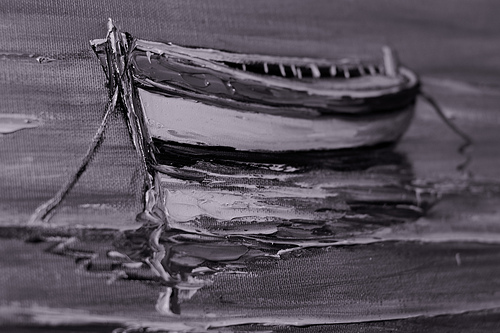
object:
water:
[46, 158, 497, 319]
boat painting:
[1, 0, 500, 333]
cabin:
[218, 60, 382, 80]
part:
[87, 17, 160, 174]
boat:
[87, 15, 422, 154]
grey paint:
[6, 44, 99, 120]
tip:
[105, 16, 119, 34]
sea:
[2, 1, 497, 333]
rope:
[28, 84, 123, 226]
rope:
[417, 84, 474, 143]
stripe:
[135, 85, 416, 150]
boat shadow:
[131, 150, 428, 318]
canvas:
[1, 0, 497, 333]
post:
[89, 17, 159, 192]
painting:
[0, 2, 500, 333]